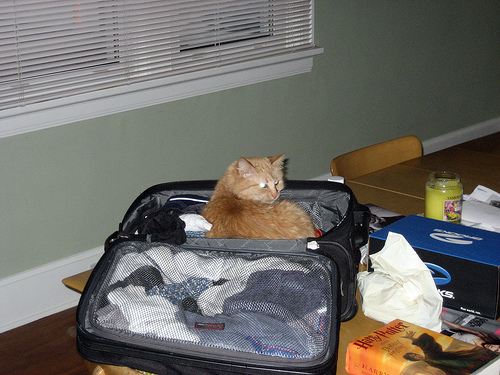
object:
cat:
[199, 151, 325, 240]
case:
[72, 175, 374, 375]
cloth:
[355, 229, 446, 334]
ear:
[236, 156, 257, 175]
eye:
[259, 182, 268, 188]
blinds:
[185, 30, 217, 33]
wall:
[1, 0, 498, 282]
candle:
[423, 162, 465, 224]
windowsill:
[0, 0, 328, 141]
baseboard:
[1, 116, 499, 374]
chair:
[329, 133, 424, 180]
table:
[1, 129, 500, 375]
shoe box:
[366, 210, 500, 320]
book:
[342, 316, 499, 375]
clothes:
[281, 282, 294, 294]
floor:
[1, 300, 91, 375]